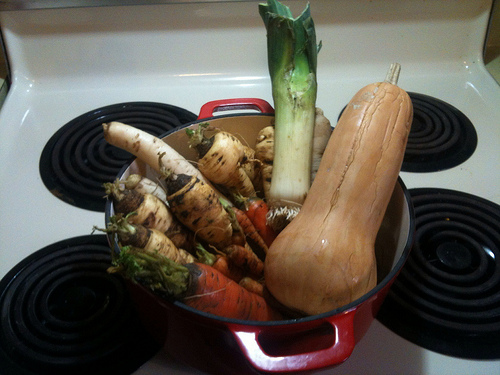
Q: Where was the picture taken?
A: In a kitchen.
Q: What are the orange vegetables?
A: Carrots.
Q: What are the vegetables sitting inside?
A: A pot.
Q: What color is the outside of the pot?
A: Red.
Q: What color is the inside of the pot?
A: White.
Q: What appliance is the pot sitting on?
A: A stove.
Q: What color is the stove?
A: White.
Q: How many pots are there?
A: One.